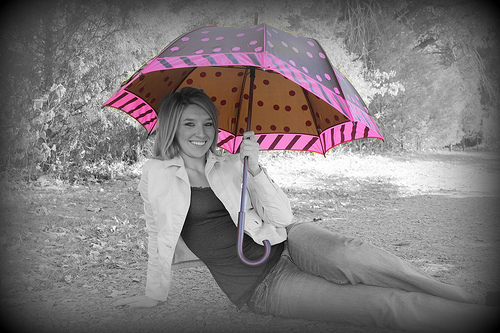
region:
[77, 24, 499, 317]
girl sitting on the ground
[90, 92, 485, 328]
girl sitting with legs outstretched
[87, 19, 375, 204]
pink and brown umbrella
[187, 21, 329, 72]
pink polka dots on brown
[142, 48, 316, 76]
brown stripes on pink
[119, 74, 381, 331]
girl smiling holding umbrella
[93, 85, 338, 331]
girl wearing white jacket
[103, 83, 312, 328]
girl wearing black shirt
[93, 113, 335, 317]
black shirt under white jacket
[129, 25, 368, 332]
umbrella with purple handle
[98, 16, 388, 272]
black and hot pink umbrella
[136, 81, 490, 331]
Girl seated on ground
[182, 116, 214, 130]
eyes on girls face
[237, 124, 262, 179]
hand holding umbrella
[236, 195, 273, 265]
handle of umbrella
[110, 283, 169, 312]
girl's hand resting on ground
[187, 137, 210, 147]
girl's mouth with smile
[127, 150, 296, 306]
white cotton front button coat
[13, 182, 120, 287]
patch of fallen leaves on ground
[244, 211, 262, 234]
flap of coat pocket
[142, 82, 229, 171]
The woman is smiling.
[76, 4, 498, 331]
The woman is sitting on the ground.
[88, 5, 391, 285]
The woman is holding an umbrella.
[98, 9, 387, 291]
The umbrella is open.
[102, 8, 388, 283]
The umbrella is pink and black.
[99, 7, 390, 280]
The umbrella has polka dots.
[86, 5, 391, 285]
The edge of the umbrella has black slashes.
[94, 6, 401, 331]
The woman is wearing a jacket.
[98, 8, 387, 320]
The woman is wearing a shirt.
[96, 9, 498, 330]
The woman is wearing pants.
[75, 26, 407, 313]
lady with umbrella over head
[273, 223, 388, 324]
pants on the lady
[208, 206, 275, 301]
bottom of the umbrella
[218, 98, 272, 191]
handle of the umbrella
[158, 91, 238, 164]
lady smiling at the camera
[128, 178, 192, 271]
white shirt on the lady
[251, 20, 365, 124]
pink and black umbrella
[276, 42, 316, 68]
pink dots on the umbrella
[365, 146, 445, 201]
light hitting the ground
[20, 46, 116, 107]
tree in the background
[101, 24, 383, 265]
the umbrella opened up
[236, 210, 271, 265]
the umbrella handle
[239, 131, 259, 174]
the hand holding the umbrella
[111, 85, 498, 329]
the woman sitting down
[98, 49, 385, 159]
the stripes on the umbrella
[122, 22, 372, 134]
the circles on the umbrella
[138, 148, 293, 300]
the light colored jacket on the woman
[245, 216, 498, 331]
the pants on the woman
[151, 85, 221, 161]
the hair on the woman's head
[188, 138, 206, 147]
the smile on the woman's face